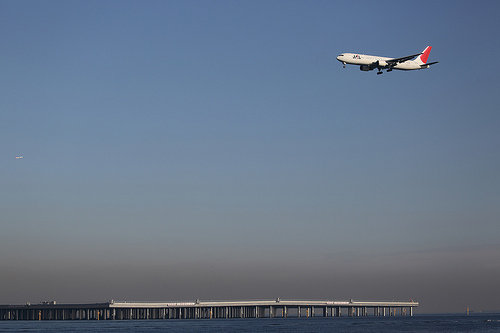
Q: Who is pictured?
A: No one.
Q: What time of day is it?
A: Day time.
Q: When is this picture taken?
A: During flight.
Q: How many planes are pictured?
A: One.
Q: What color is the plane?
A: White.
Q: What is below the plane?
A: Air strip.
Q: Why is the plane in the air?
A: Flying.